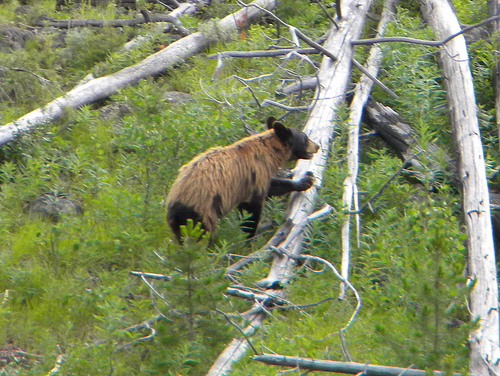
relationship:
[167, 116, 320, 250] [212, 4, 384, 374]
bear on trunk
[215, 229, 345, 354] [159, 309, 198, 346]
tree trunk on ground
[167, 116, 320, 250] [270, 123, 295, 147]
bear has ear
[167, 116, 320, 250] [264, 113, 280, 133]
bear has ear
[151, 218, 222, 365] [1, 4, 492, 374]
short pine on ground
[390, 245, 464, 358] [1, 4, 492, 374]
short pine on ground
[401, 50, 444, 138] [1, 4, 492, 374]
tree on ground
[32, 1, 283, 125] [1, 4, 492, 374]
tree on ground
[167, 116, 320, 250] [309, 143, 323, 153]
bear has nose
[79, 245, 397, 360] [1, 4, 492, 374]
branches are on ground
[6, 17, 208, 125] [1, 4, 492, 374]
tree on ground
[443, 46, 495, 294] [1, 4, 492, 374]
log on ground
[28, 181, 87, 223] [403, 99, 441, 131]
rock on ground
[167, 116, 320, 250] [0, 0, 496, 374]
bear on woods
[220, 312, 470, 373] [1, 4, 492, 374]
branch lying on ground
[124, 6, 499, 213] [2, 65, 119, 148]
tree has trunk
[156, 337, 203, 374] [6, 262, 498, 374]
plant on ground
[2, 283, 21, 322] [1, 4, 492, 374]
plant on ground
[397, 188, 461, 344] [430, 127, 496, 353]
plant near log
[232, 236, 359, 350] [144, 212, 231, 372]
branches are from trees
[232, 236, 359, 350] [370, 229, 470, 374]
branches are from trees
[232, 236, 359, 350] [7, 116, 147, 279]
branches are from trees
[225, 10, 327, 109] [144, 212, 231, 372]
branches are from trees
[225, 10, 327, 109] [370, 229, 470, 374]
branches are from trees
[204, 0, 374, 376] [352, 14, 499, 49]
tree trunk has branch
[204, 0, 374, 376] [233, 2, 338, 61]
tree trunk has branch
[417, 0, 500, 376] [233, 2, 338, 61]
tree trunk has branch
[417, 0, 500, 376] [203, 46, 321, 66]
tree trunk has branch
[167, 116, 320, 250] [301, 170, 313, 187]
bear has paws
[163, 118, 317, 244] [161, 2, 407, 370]
bear climbs tree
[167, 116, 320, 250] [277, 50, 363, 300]
bear paws tree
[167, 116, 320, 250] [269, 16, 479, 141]
bear in woods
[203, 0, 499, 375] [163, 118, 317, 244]
tree with bear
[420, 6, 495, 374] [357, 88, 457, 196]
tree trunk of tree trunk